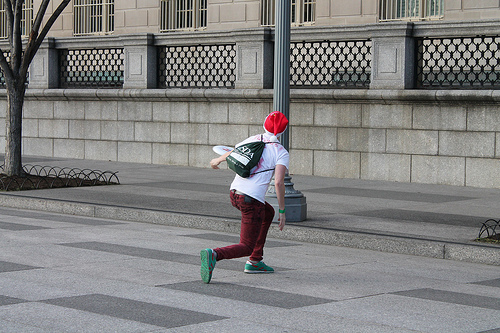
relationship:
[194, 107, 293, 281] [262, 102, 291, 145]
person wearing hat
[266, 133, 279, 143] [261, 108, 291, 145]
ball on end of hat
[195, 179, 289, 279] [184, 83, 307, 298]
pants on man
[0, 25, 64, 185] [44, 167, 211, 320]
tree in sidewalk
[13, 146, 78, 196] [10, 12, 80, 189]
dirt around tree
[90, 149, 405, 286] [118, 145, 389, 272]
curb on walkway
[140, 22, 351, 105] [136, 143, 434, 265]
concrete railing on walkway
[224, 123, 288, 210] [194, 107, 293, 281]
t shirt on person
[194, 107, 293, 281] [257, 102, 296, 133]
person wearing santa hat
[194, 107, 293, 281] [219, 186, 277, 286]
person wearing pants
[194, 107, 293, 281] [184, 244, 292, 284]
person wearing sneakers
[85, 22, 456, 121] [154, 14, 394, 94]
patterned fencing inside stone columns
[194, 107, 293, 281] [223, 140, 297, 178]
person wearing pack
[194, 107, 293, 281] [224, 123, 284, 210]
person wearing t shirt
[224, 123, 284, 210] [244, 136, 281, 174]
t shirt with lettering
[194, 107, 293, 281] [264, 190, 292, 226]
person throwing frisbee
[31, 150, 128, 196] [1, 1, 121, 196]
wire fencing along tree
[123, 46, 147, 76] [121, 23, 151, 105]
detail on stone column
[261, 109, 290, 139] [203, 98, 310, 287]
santa hat on person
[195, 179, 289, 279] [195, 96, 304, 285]
pants on person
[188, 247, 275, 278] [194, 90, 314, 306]
shoes on person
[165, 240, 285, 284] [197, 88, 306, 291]
shoe on person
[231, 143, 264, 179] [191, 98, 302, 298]
pack on person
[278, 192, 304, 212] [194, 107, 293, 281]
wristband on person